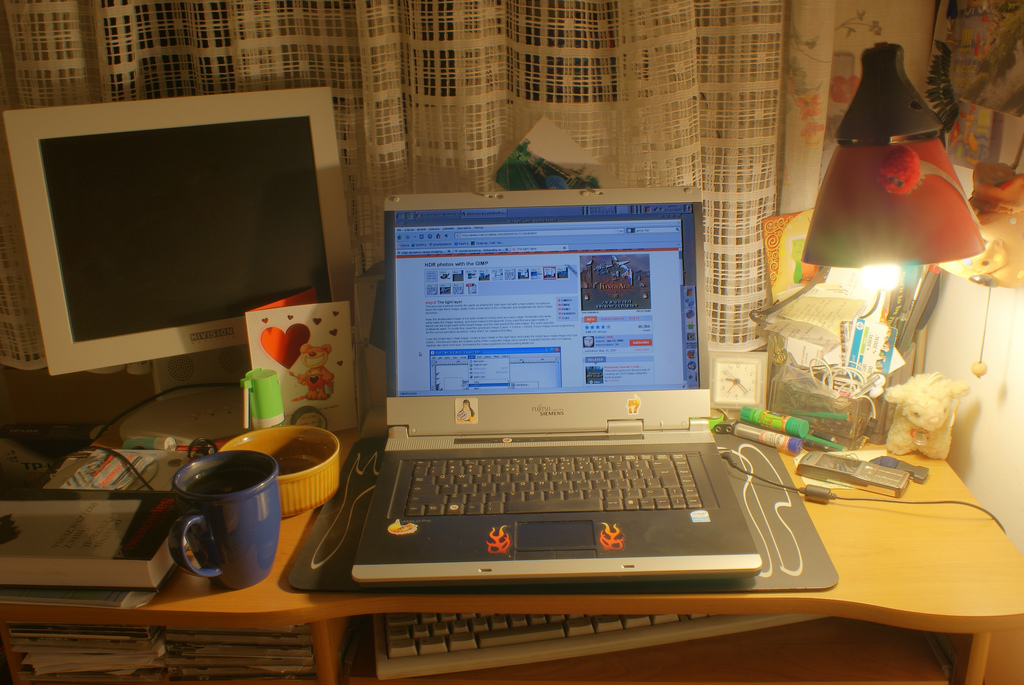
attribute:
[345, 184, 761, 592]
laptop — opened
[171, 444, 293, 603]
cup — blue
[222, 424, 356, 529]
bowl — yellow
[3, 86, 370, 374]
computer frame — white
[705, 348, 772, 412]
white clock — standard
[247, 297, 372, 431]
card — white